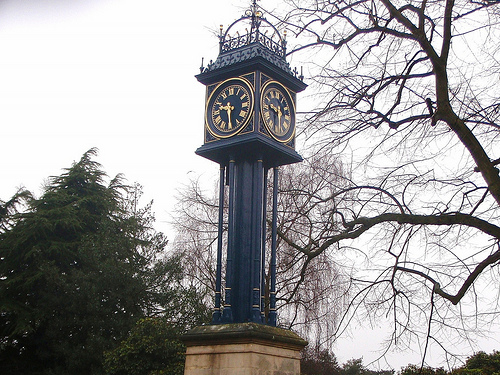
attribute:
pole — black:
[210, 156, 280, 323]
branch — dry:
[378, 0, 497, 203]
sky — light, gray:
[8, 1, 498, 372]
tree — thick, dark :
[0, 145, 152, 373]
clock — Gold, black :
[258, 79, 298, 145]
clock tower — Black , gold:
[192, 1, 310, 316]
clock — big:
[258, 75, 300, 143]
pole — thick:
[215, 161, 280, 321]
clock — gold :
[259, 78, 296, 143]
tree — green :
[2, 145, 214, 374]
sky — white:
[2, 5, 193, 141]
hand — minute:
[225, 112, 234, 132]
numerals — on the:
[240, 107, 247, 115]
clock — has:
[185, 81, 286, 143]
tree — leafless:
[307, 1, 497, 373]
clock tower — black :
[189, 11, 316, 340]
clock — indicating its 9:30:
[189, 79, 277, 133]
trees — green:
[5, 140, 202, 374]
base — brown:
[183, 347, 303, 369]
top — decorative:
[188, 4, 300, 76]